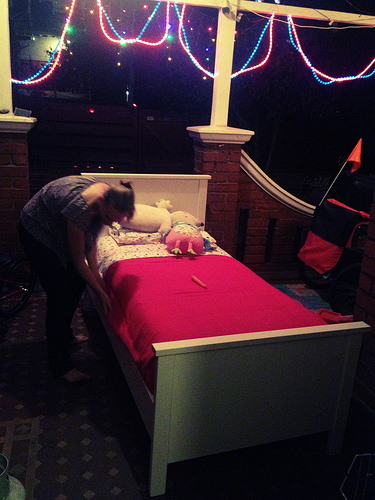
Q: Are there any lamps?
A: No, there are no lamps.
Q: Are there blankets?
A: Yes, there is a blanket.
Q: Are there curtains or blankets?
A: Yes, there is a blanket.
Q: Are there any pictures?
A: No, there are no pictures.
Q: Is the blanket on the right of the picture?
A: Yes, the blanket is on the right of the image.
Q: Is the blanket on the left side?
A: No, the blanket is on the right of the image.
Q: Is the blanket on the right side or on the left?
A: The blanket is on the right of the image.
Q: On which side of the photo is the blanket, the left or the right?
A: The blanket is on the right of the image.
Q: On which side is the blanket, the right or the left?
A: The blanket is on the right of the image.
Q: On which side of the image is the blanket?
A: The blanket is on the right of the image.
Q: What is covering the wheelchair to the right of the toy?
A: The blanket is covering the wheelchair.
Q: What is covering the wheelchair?
A: The blanket is covering the wheelchair.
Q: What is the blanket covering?
A: The blanket is covering the wheelchair.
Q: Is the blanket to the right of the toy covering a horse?
A: No, the blanket is covering the wheelchair.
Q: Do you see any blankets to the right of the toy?
A: Yes, there is a blanket to the right of the toy.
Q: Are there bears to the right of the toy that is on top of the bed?
A: No, there is a blanket to the right of the toy.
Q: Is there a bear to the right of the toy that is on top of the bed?
A: No, there is a blanket to the right of the toy.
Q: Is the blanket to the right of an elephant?
A: No, the blanket is to the right of a toy.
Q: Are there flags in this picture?
A: Yes, there is a flag.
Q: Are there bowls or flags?
A: Yes, there is a flag.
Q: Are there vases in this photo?
A: No, there are no vases.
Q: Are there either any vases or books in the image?
A: No, there are no vases or books.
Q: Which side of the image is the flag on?
A: The flag is on the right of the image.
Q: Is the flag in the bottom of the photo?
A: No, the flag is in the top of the image.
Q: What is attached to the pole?
A: The flag is attached to the pole.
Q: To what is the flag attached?
A: The flag is attached to the pole.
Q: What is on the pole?
A: The flag is on the pole.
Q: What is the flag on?
A: The flag is on the pole.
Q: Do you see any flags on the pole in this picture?
A: Yes, there is a flag on the pole.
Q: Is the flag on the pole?
A: Yes, the flag is on the pole.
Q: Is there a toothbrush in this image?
A: No, there are no toothbrushes.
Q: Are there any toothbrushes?
A: No, there are no toothbrushes.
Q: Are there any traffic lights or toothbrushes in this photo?
A: No, there are no toothbrushes or traffic lights.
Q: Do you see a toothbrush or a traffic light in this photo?
A: No, there are no toothbrushes or traffic lights.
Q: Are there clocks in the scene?
A: No, there are no clocks.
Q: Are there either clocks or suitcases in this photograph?
A: No, there are no clocks or suitcases.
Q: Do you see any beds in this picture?
A: Yes, there is a bed.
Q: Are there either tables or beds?
A: Yes, there is a bed.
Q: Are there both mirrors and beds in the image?
A: No, there is a bed but no mirrors.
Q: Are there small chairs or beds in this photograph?
A: Yes, there is a small bed.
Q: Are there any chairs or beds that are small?
A: Yes, the bed is small.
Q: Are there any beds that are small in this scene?
A: Yes, there is a small bed.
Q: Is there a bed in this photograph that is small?
A: Yes, there is a bed that is small.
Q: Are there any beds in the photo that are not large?
A: Yes, there is a small bed.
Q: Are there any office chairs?
A: No, there are no office chairs.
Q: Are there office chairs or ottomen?
A: No, there are no office chairs or ottomen.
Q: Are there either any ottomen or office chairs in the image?
A: No, there are no office chairs or ottomen.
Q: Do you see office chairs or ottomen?
A: No, there are no office chairs or ottomen.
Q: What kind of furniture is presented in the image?
A: The furniture is a bed.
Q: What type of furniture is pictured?
A: The furniture is a bed.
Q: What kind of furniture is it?
A: The piece of furniture is a bed.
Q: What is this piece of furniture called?
A: This is a bed.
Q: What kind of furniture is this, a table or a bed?
A: This is a bed.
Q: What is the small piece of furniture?
A: The piece of furniture is a bed.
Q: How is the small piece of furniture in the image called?
A: The piece of furniture is a bed.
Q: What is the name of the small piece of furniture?
A: The piece of furniture is a bed.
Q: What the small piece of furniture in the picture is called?
A: The piece of furniture is a bed.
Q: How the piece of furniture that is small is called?
A: The piece of furniture is a bed.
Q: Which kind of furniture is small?
A: The furniture is a bed.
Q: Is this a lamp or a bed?
A: This is a bed.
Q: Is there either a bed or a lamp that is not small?
A: No, there is a bed but it is small.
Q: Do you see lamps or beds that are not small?
A: No, there is a bed but it is small.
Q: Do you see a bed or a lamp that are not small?
A: No, there is a bed but it is small.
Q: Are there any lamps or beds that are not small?
A: No, there is a bed but it is small.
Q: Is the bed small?
A: Yes, the bed is small.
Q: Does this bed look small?
A: Yes, the bed is small.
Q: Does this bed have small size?
A: Yes, the bed is small.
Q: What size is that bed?
A: The bed is small.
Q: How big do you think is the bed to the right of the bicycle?
A: The bed is small.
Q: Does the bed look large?
A: No, the bed is small.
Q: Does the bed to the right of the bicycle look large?
A: No, the bed is small.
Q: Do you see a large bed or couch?
A: No, there is a bed but it is small.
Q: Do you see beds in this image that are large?
A: No, there is a bed but it is small.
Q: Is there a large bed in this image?
A: No, there is a bed but it is small.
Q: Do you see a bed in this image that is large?
A: No, there is a bed but it is small.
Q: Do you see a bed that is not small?
A: No, there is a bed but it is small.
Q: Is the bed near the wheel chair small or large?
A: The bed is small.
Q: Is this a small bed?
A: Yes, this is a small bed.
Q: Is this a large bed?
A: No, this is a small bed.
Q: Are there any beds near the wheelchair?
A: Yes, there is a bed near the wheelchair.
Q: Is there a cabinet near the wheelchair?
A: No, there is a bed near the wheelchair.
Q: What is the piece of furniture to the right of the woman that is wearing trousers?
A: The piece of furniture is a bed.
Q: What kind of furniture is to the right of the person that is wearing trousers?
A: The piece of furniture is a bed.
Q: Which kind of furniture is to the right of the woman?
A: The piece of furniture is a bed.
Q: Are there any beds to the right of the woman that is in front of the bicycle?
A: Yes, there is a bed to the right of the woman.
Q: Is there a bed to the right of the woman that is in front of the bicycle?
A: Yes, there is a bed to the right of the woman.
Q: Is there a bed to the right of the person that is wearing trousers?
A: Yes, there is a bed to the right of the woman.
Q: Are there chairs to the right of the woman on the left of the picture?
A: No, there is a bed to the right of the woman.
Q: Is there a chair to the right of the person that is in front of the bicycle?
A: No, there is a bed to the right of the woman.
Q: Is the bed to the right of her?
A: Yes, the bed is to the right of the woman.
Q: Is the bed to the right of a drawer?
A: No, the bed is to the right of the woman.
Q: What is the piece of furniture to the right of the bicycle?
A: The piece of furniture is a bed.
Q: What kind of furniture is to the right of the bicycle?
A: The piece of furniture is a bed.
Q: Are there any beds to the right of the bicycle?
A: Yes, there is a bed to the right of the bicycle.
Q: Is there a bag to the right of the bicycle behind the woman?
A: No, there is a bed to the right of the bicycle.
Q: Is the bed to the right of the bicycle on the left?
A: Yes, the bed is to the right of the bicycle.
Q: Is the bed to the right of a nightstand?
A: No, the bed is to the right of the bicycle.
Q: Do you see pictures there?
A: No, there are no pictures.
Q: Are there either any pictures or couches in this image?
A: No, there are no pictures or couches.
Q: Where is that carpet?
A: The carpet is on the floor.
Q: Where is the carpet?
A: The carpet is on the floor.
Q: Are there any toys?
A: Yes, there is a toy.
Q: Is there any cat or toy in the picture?
A: Yes, there is a toy.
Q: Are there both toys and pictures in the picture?
A: No, there is a toy but no pictures.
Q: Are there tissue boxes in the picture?
A: No, there are no tissue boxes.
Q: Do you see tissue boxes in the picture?
A: No, there are no tissue boxes.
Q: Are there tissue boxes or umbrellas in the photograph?
A: No, there are no tissue boxes or umbrellas.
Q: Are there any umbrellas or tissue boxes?
A: No, there are no tissue boxes or umbrellas.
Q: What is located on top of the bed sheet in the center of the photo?
A: The toy is on top of the bed sheet.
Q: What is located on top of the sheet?
A: The toy is on top of the bed sheet.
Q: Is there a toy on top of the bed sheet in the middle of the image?
A: Yes, there is a toy on top of the sheet.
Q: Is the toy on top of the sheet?
A: Yes, the toy is on top of the sheet.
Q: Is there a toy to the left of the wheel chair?
A: Yes, there is a toy to the left of the wheel chair.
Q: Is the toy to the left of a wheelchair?
A: Yes, the toy is to the left of a wheelchair.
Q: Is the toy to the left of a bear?
A: No, the toy is to the left of a wheelchair.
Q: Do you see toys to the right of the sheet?
A: Yes, there is a toy to the right of the sheet.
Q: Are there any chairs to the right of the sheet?
A: No, there is a toy to the right of the sheet.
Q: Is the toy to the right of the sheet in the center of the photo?
A: Yes, the toy is to the right of the sheet.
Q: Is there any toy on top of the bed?
A: Yes, there is a toy on top of the bed.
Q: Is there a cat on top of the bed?
A: No, there is a toy on top of the bed.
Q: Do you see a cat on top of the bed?
A: No, there is a toy on top of the bed.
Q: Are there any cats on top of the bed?
A: No, there is a toy on top of the bed.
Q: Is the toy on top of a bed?
A: Yes, the toy is on top of a bed.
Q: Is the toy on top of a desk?
A: No, the toy is on top of a bed.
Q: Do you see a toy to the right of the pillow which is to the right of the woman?
A: Yes, there is a toy to the right of the pillow.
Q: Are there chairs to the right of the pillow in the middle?
A: No, there is a toy to the right of the pillow.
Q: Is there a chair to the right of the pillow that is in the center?
A: No, there is a toy to the right of the pillow.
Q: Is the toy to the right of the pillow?
A: Yes, the toy is to the right of the pillow.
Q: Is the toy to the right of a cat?
A: No, the toy is to the right of the pillow.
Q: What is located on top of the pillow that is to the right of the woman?
A: The toy is on top of the pillow.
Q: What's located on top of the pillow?
A: The toy is on top of the pillow.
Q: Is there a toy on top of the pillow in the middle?
A: Yes, there is a toy on top of the pillow.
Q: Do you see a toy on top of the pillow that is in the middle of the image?
A: Yes, there is a toy on top of the pillow.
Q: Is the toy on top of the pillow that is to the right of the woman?
A: Yes, the toy is on top of the pillow.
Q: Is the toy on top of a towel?
A: No, the toy is on top of the pillow.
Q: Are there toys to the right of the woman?
A: Yes, there is a toy to the right of the woman.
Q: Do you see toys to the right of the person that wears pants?
A: Yes, there is a toy to the right of the woman.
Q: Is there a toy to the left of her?
A: No, the toy is to the right of the woman.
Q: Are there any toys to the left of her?
A: No, the toy is to the right of the woman.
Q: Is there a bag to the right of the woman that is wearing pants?
A: No, there is a toy to the right of the woman.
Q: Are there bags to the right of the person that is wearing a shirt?
A: No, there is a toy to the right of the woman.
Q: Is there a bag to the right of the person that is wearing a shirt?
A: No, there is a toy to the right of the woman.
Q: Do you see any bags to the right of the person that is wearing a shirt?
A: No, there is a toy to the right of the woman.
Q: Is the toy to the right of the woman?
A: Yes, the toy is to the right of the woman.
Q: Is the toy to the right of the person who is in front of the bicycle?
A: Yes, the toy is to the right of the woman.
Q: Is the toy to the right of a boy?
A: No, the toy is to the right of the woman.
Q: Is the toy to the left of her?
A: No, the toy is to the right of the woman.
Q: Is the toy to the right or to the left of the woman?
A: The toy is to the right of the woman.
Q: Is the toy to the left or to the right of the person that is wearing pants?
A: The toy is to the right of the woman.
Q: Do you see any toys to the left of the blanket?
A: Yes, there is a toy to the left of the blanket.